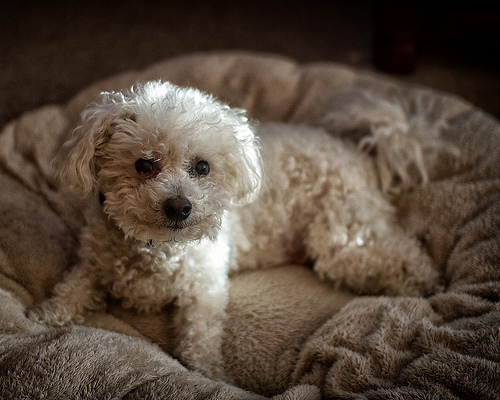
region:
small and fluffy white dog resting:
[30, 65, 440, 382]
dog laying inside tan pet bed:
[0, 46, 495, 391]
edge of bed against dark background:
[10, 5, 492, 150]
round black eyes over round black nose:
[130, 151, 210, 223]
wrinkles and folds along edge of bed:
[291, 56, 496, 386]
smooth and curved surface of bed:
[1, 300, 241, 395]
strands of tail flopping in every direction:
[320, 71, 465, 191]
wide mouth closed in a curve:
[127, 205, 212, 240]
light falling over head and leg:
[125, 66, 260, 291]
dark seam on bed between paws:
[27, 287, 265, 377]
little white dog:
[27, 93, 437, 374]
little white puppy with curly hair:
[40, 90, 447, 367]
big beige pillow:
[3, 48, 493, 398]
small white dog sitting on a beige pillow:
[5, 53, 497, 393]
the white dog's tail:
[335, 89, 447, 179]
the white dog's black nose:
[164, 193, 194, 220]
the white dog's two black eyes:
[131, 157, 211, 179]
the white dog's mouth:
[135, 214, 207, 232]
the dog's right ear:
[63, 98, 106, 191]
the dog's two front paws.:
[40, 293, 228, 378]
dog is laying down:
[0, 48, 476, 393]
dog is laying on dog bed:
[2, 25, 499, 398]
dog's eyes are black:
[118, 143, 221, 183]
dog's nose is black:
[152, 189, 216, 229]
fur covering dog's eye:
[128, 145, 165, 163]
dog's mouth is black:
[118, 215, 210, 240]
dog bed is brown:
[0, 33, 492, 391]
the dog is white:
[22, 77, 471, 371]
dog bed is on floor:
[3, 0, 493, 394]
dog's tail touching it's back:
[317, 82, 454, 200]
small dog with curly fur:
[89, 106, 249, 261]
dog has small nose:
[151, 192, 196, 223]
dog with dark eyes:
[123, 153, 223, 182]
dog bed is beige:
[266, 309, 297, 333]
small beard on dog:
[125, 228, 232, 263]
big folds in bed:
[291, 308, 393, 384]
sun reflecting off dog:
[177, 226, 272, 279]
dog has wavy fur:
[75, 100, 105, 185]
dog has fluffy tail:
[351, 118, 461, 222]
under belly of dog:
[236, 233, 314, 270]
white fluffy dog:
[50, 63, 460, 384]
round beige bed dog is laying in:
[3, 42, 496, 399]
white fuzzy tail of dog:
[326, 75, 453, 182]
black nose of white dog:
[164, 198, 191, 225]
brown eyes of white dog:
[129, 153, 209, 175]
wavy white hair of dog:
[58, 81, 393, 336]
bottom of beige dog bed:
[109, 265, 416, 376]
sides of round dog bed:
[13, 64, 490, 391]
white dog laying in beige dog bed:
[15, 63, 494, 399]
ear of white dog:
[53, 101, 268, 206]